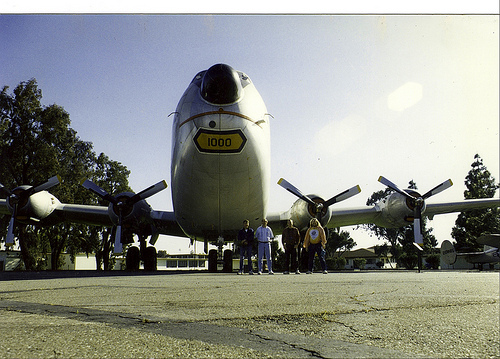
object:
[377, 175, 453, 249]
propeller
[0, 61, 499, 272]
plane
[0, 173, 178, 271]
wing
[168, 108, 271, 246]
fuselage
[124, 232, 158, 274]
landing gear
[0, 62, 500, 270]
airplane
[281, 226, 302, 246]
shirt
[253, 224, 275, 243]
shirt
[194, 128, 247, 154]
plaque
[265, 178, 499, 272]
wing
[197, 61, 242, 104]
nose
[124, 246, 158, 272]
tire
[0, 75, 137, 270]
tree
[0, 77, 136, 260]
leaves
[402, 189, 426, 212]
engine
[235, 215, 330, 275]
man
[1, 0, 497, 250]
sky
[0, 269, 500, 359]
concrete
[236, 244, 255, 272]
jeans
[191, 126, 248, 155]
sign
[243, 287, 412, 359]
crack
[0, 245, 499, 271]
buildings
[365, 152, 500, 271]
tree